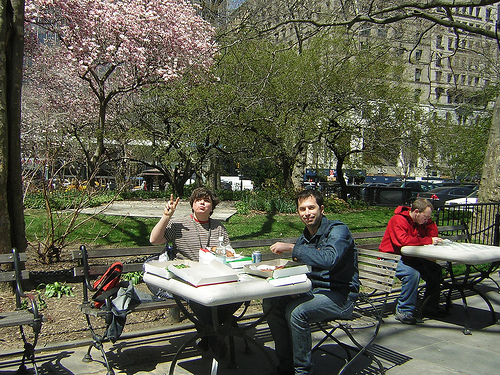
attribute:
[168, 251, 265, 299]
box — white 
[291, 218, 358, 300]
jacket — blue 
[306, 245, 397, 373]
park bench — wooden 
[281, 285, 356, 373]
jeans — blue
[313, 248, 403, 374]
bench — wooden 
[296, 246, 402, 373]
chair — wooden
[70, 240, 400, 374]
bench — wooden 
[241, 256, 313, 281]
box — white 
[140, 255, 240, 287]
cardboard box — white, opened up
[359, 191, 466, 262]
hoodie — red 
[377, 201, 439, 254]
sweatshirt — white red 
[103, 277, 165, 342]
jacket — jean 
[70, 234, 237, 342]
bench — wooden 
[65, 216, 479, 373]
bench — brown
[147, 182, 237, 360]
boy — young 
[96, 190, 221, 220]
slab — square , cement 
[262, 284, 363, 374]
jeans — blue 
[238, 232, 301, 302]
box — white 